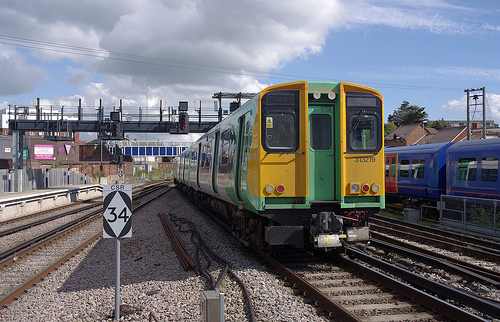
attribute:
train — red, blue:
[386, 131, 498, 211]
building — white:
[121, 124, 193, 164]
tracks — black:
[233, 210, 498, 285]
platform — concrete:
[156, 174, 221, 276]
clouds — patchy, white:
[4, 1, 473, 107]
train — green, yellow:
[144, 82, 409, 249]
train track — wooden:
[331, 287, 388, 299]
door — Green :
[306, 104, 346, 200]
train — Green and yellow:
[160, 87, 387, 245]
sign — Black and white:
[101, 182, 133, 239]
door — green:
[306, 100, 338, 201]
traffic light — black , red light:
[169, 94, 195, 135]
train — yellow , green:
[174, 73, 394, 256]